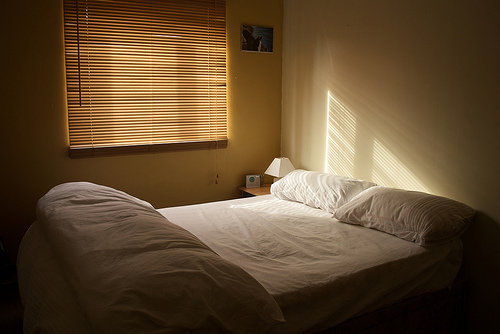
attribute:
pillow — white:
[321, 185, 492, 254]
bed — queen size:
[22, 166, 473, 332]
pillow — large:
[21, 170, 274, 332]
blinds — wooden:
[55, 3, 238, 149]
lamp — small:
[256, 144, 296, 194]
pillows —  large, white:
[274, 167, 486, 246]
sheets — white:
[220, 202, 344, 269]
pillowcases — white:
[277, 174, 353, 213]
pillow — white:
[332, 180, 492, 253]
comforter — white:
[33, 180, 268, 330]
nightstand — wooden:
[239, 178, 289, 199]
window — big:
[57, 5, 242, 157]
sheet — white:
[148, 187, 431, 305]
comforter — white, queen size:
[12, 172, 284, 326]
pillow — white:
[268, 165, 376, 213]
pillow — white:
[329, 183, 483, 249]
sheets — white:
[153, 190, 420, 316]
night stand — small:
[239, 185, 275, 198]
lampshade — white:
[263, 153, 295, 177]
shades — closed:
[181, 111, 217, 135]